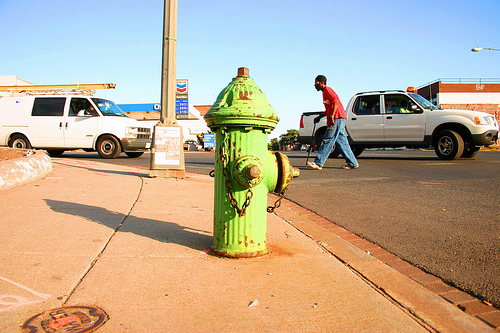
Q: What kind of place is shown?
A: It is a sidewalk.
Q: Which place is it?
A: It is a sidewalk.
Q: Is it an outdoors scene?
A: Yes, it is outdoors.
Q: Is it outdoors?
A: Yes, it is outdoors.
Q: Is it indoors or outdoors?
A: It is outdoors.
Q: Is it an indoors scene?
A: No, it is outdoors.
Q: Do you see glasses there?
A: No, there are no glasses.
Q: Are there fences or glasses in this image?
A: No, there are no glasses or fences.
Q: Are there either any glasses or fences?
A: No, there are no glasses or fences.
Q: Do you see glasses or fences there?
A: No, there are no glasses or fences.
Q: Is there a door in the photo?
A: Yes, there is a door.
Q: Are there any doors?
A: Yes, there is a door.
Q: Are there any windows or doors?
A: Yes, there is a door.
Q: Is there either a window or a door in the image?
A: Yes, there is a door.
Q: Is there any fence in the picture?
A: No, there are no fences.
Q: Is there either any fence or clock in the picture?
A: No, there are no fences or clocks.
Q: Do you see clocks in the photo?
A: No, there are no clocks.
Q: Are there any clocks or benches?
A: No, there are no clocks or benches.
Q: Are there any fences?
A: No, there are no fences.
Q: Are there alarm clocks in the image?
A: No, there are no alarm clocks.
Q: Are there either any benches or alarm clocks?
A: No, there are no alarm clocks or benches.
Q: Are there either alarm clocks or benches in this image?
A: No, there are no alarm clocks or benches.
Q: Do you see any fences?
A: No, there are no fences.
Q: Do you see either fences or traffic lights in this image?
A: No, there are no fences or traffic lights.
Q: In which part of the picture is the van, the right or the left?
A: The van is on the left of the image.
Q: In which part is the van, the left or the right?
A: The van is on the left of the image.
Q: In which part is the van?
A: The van is on the left of the image.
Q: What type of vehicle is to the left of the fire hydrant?
A: The vehicle is a van.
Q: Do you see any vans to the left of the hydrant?
A: Yes, there is a van to the left of the hydrant.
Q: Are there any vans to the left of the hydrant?
A: Yes, there is a van to the left of the hydrant.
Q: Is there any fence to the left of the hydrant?
A: No, there is a van to the left of the hydrant.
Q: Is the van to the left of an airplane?
A: No, the van is to the left of the fire hydrant.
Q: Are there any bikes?
A: No, there are no bikes.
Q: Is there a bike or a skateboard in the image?
A: No, there are no bikes or skateboards.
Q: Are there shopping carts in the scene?
A: No, there are no shopping carts.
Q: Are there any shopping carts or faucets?
A: No, there are no shopping carts or faucets.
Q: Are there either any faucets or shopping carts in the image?
A: No, there are no shopping carts or faucets.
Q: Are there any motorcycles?
A: No, there are no motorcycles.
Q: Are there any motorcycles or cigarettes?
A: No, there are no motorcycles or cigarettes.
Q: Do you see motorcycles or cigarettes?
A: No, there are no motorcycles or cigarettes.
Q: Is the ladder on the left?
A: Yes, the ladder is on the left of the image.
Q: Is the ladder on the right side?
A: No, the ladder is on the left of the image.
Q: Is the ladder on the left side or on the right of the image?
A: The ladder is on the left of the image.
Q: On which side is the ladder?
A: The ladder is on the left of the image.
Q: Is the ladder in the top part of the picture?
A: Yes, the ladder is in the top of the image.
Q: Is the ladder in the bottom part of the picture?
A: No, the ladder is in the top of the image.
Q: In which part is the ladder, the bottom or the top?
A: The ladder is in the top of the image.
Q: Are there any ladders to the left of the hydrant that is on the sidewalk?
A: Yes, there is a ladder to the left of the hydrant.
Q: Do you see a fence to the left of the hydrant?
A: No, there is a ladder to the left of the hydrant.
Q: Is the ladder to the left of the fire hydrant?
A: Yes, the ladder is to the left of the fire hydrant.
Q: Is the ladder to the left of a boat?
A: No, the ladder is to the left of the fire hydrant.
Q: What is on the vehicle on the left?
A: The ladder is on the van.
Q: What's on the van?
A: The ladder is on the van.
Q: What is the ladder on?
A: The ladder is on the van.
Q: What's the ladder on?
A: The ladder is on the van.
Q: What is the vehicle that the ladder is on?
A: The vehicle is a van.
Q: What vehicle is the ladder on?
A: The ladder is on the van.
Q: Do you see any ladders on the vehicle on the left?
A: Yes, there is a ladder on the van.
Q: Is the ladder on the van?
A: Yes, the ladder is on the van.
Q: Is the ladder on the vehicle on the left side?
A: Yes, the ladder is on the van.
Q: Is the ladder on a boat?
A: No, the ladder is on the van.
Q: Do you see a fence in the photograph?
A: No, there are no fences.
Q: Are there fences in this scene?
A: No, there are no fences.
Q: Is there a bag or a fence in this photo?
A: No, there are no fences or bags.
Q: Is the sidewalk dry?
A: Yes, the sidewalk is dry.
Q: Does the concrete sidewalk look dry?
A: Yes, the sidewalk is dry.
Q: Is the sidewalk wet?
A: No, the sidewalk is dry.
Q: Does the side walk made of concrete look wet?
A: No, the sidewalk is dry.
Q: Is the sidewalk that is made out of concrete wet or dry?
A: The sidewalk is dry.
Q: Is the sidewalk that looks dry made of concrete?
A: Yes, the side walk is made of concrete.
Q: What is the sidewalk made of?
A: The sidewalk is made of concrete.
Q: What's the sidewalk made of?
A: The sidewalk is made of concrete.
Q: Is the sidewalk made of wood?
A: No, the sidewalk is made of cement.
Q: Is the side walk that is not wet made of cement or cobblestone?
A: The sidewalk is made of cement.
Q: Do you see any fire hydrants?
A: Yes, there is a fire hydrant.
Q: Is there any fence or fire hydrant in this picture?
A: Yes, there is a fire hydrant.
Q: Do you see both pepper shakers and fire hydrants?
A: No, there is a fire hydrant but no pepper shakers.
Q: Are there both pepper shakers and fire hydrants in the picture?
A: No, there is a fire hydrant but no pepper shakers.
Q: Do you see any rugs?
A: No, there are no rugs.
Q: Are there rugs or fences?
A: No, there are no rugs or fences.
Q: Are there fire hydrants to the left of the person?
A: Yes, there is a fire hydrant to the left of the person.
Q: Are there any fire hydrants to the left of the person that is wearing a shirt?
A: Yes, there is a fire hydrant to the left of the person.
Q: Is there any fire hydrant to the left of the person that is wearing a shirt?
A: Yes, there is a fire hydrant to the left of the person.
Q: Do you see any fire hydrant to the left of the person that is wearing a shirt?
A: Yes, there is a fire hydrant to the left of the person.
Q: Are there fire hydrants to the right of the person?
A: No, the fire hydrant is to the left of the person.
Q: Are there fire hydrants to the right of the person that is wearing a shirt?
A: No, the fire hydrant is to the left of the person.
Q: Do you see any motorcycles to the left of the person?
A: No, there is a fire hydrant to the left of the person.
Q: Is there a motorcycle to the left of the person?
A: No, there is a fire hydrant to the left of the person.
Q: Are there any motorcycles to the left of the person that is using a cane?
A: No, there is a fire hydrant to the left of the person.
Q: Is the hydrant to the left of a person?
A: Yes, the hydrant is to the left of a person.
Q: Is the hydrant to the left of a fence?
A: No, the hydrant is to the left of a person.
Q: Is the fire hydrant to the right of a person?
A: No, the fire hydrant is to the left of a person.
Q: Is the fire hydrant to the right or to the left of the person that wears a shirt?
A: The fire hydrant is to the left of the person.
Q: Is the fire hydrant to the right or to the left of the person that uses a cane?
A: The fire hydrant is to the left of the person.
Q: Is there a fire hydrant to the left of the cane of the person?
A: Yes, there is a fire hydrant to the left of the cane.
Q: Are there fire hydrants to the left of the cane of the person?
A: Yes, there is a fire hydrant to the left of the cane.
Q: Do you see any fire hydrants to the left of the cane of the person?
A: Yes, there is a fire hydrant to the left of the cane.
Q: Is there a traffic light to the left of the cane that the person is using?
A: No, there is a fire hydrant to the left of the cane.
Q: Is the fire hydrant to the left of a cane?
A: Yes, the fire hydrant is to the left of a cane.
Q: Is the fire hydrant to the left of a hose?
A: No, the fire hydrant is to the left of a cane.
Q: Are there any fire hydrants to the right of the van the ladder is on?
A: Yes, there is a fire hydrant to the right of the van.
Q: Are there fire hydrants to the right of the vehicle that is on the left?
A: Yes, there is a fire hydrant to the right of the van.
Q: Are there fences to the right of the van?
A: No, there is a fire hydrant to the right of the van.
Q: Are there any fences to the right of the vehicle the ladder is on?
A: No, there is a fire hydrant to the right of the van.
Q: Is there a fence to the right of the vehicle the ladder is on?
A: No, there is a fire hydrant to the right of the van.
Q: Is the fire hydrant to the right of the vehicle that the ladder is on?
A: Yes, the fire hydrant is to the right of the van.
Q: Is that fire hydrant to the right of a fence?
A: No, the fire hydrant is to the right of the van.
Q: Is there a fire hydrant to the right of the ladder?
A: Yes, there is a fire hydrant to the right of the ladder.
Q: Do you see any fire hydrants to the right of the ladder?
A: Yes, there is a fire hydrant to the right of the ladder.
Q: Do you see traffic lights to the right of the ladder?
A: No, there is a fire hydrant to the right of the ladder.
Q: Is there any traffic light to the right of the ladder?
A: No, there is a fire hydrant to the right of the ladder.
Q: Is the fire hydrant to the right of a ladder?
A: Yes, the fire hydrant is to the right of a ladder.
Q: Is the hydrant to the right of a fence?
A: No, the hydrant is to the right of a ladder.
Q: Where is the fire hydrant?
A: The fire hydrant is on the sidewalk.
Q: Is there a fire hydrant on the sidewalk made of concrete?
A: Yes, there is a fire hydrant on the sidewalk.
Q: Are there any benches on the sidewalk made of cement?
A: No, there is a fire hydrant on the sidewalk.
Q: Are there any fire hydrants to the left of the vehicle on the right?
A: Yes, there is a fire hydrant to the left of the vehicle.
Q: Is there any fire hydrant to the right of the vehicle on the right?
A: No, the fire hydrant is to the left of the vehicle.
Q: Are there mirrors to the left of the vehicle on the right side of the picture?
A: No, there is a fire hydrant to the left of the vehicle.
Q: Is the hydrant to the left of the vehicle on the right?
A: Yes, the hydrant is to the left of the vehicle.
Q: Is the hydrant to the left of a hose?
A: No, the hydrant is to the left of the vehicle.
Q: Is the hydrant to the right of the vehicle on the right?
A: No, the hydrant is to the left of the vehicle.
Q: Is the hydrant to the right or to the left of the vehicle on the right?
A: The hydrant is to the left of the vehicle.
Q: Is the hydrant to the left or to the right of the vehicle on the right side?
A: The hydrant is to the left of the vehicle.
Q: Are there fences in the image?
A: No, there are no fences.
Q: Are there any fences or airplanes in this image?
A: No, there are no fences or airplanes.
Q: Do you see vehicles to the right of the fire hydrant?
A: Yes, there is a vehicle to the right of the fire hydrant.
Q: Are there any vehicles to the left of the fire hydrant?
A: No, the vehicle is to the right of the fire hydrant.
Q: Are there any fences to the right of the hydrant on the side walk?
A: No, there is a vehicle to the right of the hydrant.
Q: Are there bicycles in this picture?
A: No, there are no bicycles.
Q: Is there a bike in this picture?
A: No, there are no bikes.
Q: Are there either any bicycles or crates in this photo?
A: No, there are no bicycles or crates.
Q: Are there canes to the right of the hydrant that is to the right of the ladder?
A: Yes, there is a cane to the right of the hydrant.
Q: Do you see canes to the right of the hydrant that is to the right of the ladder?
A: Yes, there is a cane to the right of the hydrant.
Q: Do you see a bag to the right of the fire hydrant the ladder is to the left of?
A: No, there is a cane to the right of the hydrant.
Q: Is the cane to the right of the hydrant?
A: Yes, the cane is to the right of the hydrant.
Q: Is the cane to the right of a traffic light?
A: No, the cane is to the right of the hydrant.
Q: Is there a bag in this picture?
A: No, there are no bags.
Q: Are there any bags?
A: No, there are no bags.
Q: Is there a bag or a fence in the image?
A: No, there are no bags or fences.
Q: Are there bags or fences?
A: No, there are no bags or fences.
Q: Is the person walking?
A: Yes, the person is walking.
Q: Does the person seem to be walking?
A: Yes, the person is walking.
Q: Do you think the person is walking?
A: Yes, the person is walking.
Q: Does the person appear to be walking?
A: Yes, the person is walking.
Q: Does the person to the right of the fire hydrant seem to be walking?
A: Yes, the person is walking.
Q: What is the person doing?
A: The person is walking.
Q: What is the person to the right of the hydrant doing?
A: The person is walking.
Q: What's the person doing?
A: The person is walking.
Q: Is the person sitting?
A: No, the person is walking.